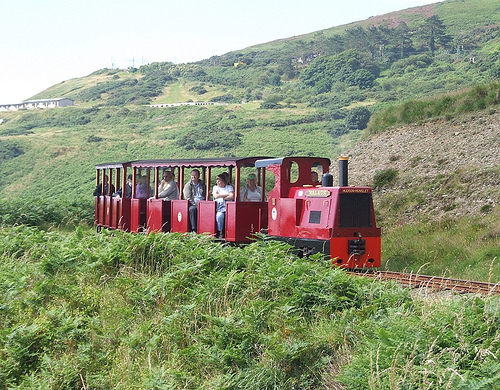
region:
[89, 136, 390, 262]
red train on track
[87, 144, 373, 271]
passengers on little red train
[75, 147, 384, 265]
train carrying passengers on tracks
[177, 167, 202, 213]
man in tan jacket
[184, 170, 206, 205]
man in tan jacket on train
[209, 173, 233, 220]
woman with shades looking back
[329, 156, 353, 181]
black smoke stack on train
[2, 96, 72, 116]
building on top of hill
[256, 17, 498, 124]
thick green trees on hill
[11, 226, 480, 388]
lush green grass along train tracks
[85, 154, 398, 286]
red train moving along tracks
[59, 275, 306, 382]
lots of grass growing along countrside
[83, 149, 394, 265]
people riding on red train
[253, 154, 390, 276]
front engine of the train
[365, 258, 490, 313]
steel tracks for train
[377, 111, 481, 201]
dirt on the hillside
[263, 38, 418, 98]
trees on the mountain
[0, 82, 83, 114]
white building in the background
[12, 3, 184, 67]
gray sky above the mountain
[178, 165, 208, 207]
man wearing a jacket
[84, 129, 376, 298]
train on the tracks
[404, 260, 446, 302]
track under the train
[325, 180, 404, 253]
front of the train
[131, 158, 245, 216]
people in the train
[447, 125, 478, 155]
rocks next to the grass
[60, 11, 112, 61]
sky above the land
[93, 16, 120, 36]
sky with no clouds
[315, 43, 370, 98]
trees in the distance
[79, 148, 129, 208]
back of the train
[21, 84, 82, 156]
building in the background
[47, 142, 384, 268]
The train is red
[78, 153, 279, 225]
There are people on the train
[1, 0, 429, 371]
The hills are grassy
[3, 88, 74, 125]
A building on the hillside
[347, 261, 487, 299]
Train tracks in front of the train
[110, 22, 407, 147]
The hill has trees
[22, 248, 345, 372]
The hillside is very green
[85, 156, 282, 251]
The train has two cars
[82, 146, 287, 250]
The train is carrying passengers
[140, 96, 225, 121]
Building on the hillside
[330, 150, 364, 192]
small black funnel on front of train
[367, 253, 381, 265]
holes in front of the train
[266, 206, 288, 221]
white circle on side of train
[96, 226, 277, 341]
overgrown area of green bush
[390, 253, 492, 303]
red train tracks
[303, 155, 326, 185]
conductor sitting in front of train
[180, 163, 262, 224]
people sitting in train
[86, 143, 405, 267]
small red train on track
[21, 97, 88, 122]
houses in the far off distance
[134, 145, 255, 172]
black roof on train